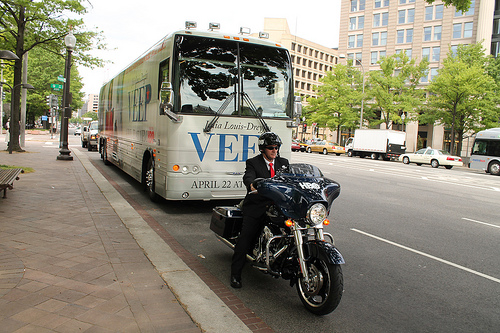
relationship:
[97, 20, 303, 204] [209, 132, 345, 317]
bus behind motorcycle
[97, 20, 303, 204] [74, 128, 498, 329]
bus sitting on street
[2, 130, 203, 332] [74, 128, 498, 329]
sidewalk beside of street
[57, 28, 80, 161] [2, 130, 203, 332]
lamp post on sidewalk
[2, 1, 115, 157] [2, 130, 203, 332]
tree on sidewalk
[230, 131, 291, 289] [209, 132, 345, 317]
man sitting on a motorcycle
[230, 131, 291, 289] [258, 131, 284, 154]
man wearing a helmet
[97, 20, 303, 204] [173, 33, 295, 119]
bus has a windshield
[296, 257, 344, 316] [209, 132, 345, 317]
tire on motorcycle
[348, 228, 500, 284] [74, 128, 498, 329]
line on street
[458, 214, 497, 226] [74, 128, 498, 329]
line on street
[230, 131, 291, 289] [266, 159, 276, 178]
man wearing a tie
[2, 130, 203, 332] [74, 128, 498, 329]
sidewalk beside street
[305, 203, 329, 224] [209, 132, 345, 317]
headlight on motorcycle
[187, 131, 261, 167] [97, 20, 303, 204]
letters are on bus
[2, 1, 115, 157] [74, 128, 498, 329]
tree beside of street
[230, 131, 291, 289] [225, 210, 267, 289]
man has a leg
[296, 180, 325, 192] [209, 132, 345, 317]
logo on motorcycle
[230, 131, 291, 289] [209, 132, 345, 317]
man riding motorcycle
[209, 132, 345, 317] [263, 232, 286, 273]
motorcycle has an engine guard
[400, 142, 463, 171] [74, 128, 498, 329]
cab parked on street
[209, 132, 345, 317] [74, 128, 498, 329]
motorcycle sitting on street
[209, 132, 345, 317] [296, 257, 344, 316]
motorcycle has a tire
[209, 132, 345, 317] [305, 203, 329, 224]
motorcycle has a headlight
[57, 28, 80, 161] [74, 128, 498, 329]
lamp post beside street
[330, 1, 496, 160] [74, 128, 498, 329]
building beside street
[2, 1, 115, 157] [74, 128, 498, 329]
tree beside street